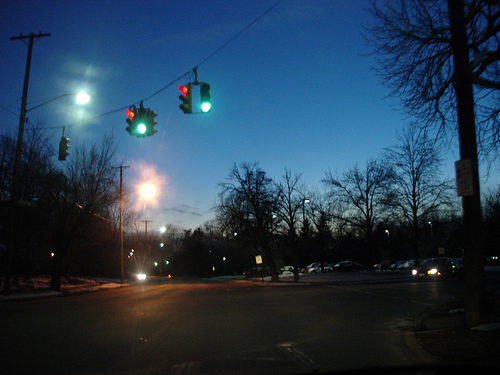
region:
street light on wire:
[174, 76, 221, 117]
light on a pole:
[297, 190, 314, 280]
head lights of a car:
[134, 270, 153, 283]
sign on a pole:
[253, 256, 265, 269]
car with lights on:
[410, 255, 454, 284]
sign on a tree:
[444, 151, 486, 203]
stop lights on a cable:
[39, 66, 249, 166]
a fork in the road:
[162, 249, 432, 358]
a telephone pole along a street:
[112, 159, 129, 286]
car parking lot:
[279, 255, 417, 285]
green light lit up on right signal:
[196, 95, 222, 127]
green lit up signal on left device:
[129, 115, 160, 144]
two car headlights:
[133, 264, 161, 295]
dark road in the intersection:
[218, 293, 282, 322]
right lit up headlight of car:
[393, 260, 421, 288]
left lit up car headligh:
[422, 261, 435, 283]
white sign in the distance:
[247, 245, 274, 277]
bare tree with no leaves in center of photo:
[227, 163, 283, 223]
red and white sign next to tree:
[428, 141, 485, 218]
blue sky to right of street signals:
[233, 55, 350, 131]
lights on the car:
[425, 268, 437, 275]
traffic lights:
[167, 81, 217, 116]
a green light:
[198, 100, 212, 113]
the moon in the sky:
[73, 91, 93, 106]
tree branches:
[70, 148, 110, 188]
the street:
[55, 288, 367, 357]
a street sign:
[450, 160, 476, 196]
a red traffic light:
[120, 108, 136, 118]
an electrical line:
[193, 47, 228, 64]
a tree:
[257, 202, 287, 284]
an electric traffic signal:
[195, 82, 212, 114]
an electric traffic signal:
[175, 80, 190, 116]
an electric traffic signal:
[131, 103, 146, 139]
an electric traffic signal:
[146, 108, 160, 138]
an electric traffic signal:
[123, 101, 133, 135]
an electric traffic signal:
[54, 133, 71, 165]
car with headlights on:
[405, 255, 453, 285]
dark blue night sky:
[0, 2, 495, 236]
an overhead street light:
[21, 86, 98, 125]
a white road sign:
[250, 252, 265, 264]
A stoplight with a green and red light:
[124, 104, 164, 141]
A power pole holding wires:
[111, 162, 133, 286]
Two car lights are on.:
[136, 271, 151, 284]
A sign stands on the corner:
[256, 254, 266, 286]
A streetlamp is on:
[26, 88, 96, 109]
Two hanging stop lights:
[121, 85, 231, 145]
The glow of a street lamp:
[122, 177, 164, 207]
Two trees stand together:
[349, 156, 426, 260]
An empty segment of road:
[148, 290, 313, 331]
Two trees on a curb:
[246, 237, 309, 288]